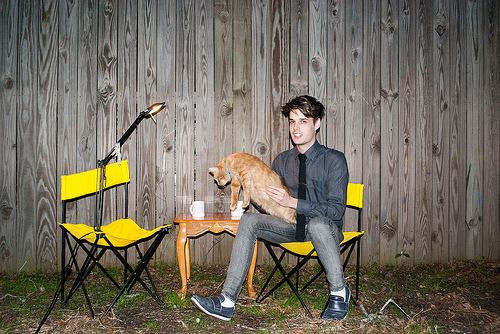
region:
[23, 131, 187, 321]
Bright yellow lawn chair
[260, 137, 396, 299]
Bright yellow lawn chair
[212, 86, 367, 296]
PErson sitting in a chair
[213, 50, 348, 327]
Man holding a cat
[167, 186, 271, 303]
Small brown end table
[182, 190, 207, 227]
White cup on the table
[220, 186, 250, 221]
White cup on the table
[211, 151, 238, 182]
Blue collar around cats neck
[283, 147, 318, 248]
Black tie around neck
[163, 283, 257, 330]
Blue and white shoe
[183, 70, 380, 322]
guy holding a cat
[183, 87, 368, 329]
guy with short black hair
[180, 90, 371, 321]
guy wearing a grey shirt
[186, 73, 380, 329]
guy wearing a black tie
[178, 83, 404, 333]
guy wearing washed out denim jeans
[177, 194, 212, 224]
white mug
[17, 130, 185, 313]
yellow chair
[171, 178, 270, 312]
two white mugs on a end table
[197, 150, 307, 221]
light brown kitten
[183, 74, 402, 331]
guy sitting near a fence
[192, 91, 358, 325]
Young man holding cat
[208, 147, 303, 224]
Cat is looking down at table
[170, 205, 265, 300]
Wooden table behind young man and cat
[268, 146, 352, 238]
Young man is wearing blue shirt with black tight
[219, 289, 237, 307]
Young man has on white socks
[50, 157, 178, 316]
Yellow camping chair with black base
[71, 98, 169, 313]
Light facing table and cat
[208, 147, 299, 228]
Orange cat wearing a blue collar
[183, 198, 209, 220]
Coffee mug sitting on table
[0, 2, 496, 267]
Wooden fence behind young man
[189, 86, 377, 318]
Man holding an animal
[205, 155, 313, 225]
The animal is a cat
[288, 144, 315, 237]
Man is wearing a black tie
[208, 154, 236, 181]
Cat is wearing a blue collar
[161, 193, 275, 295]
Small wooden table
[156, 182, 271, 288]
The table has two white cups on it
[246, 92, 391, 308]
The man is in a yellow chair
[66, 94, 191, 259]
There is a lamp sitting on this chair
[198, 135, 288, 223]
The left side of the cat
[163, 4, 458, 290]
There is a wooden fence behind the man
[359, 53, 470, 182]
long wooden fence in the back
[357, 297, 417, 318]
broken twigs on the ground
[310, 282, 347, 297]
man wearing white sock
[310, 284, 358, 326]
blue loafers on man's foot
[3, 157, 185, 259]
chair with yellow seat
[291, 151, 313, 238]
long black thin tie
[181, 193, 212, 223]
white mug on table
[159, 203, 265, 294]
small brown wooden table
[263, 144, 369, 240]
long sleeve gray shirt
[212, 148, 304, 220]
brown cat in man's hand